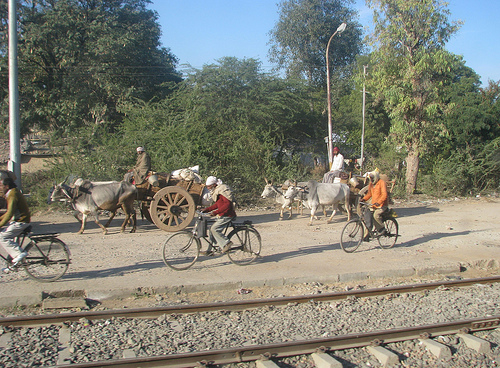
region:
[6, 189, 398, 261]
people riding bikes on a dirt road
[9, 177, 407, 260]
people riding bikes near a train track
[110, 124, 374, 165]
people riding on a carriage on a dirt road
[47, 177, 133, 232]
ox pulling the carriage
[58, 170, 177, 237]
a carriage attached to ox.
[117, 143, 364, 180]
people driving a carriage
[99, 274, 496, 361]
train tracks located near a dirt road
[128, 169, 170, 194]
a bucket hanging from a carriage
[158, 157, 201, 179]
bags strapped onto a carriage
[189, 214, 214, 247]
a bag hanging from a bike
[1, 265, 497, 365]
train tracks on the ground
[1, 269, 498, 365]
gravel on the train tracks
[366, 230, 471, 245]
shadow on the ground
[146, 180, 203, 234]
large wheel on the side of the carriage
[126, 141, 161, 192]
man sitting on the carriage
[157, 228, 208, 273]
wheel on the front of the bike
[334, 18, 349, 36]
light on top of the pole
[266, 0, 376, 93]
green leaves on the tree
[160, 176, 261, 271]
a man riding bicycle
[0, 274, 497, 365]
a set of railroad tracks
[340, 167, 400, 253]
a man riding a bicycle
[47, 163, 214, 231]
oxen pulling a cart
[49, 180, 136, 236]
a grey and white ox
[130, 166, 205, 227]
a brown wooden cart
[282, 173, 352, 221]
a white grey ox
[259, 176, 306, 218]
a white grey ox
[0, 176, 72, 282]
a man riding a bicycle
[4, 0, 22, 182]
a tall metal pole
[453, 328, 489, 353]
wooden board on tracks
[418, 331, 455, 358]
wooden board on tracks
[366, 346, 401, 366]
wooden board on tracks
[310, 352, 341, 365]
wooden board on tracks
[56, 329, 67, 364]
wooden board on tracks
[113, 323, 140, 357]
wooden board on tracks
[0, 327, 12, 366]
wooden board on tracks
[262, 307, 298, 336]
wooden board on tracks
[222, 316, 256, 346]
wooden board on tracks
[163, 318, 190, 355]
wooden board on tracks